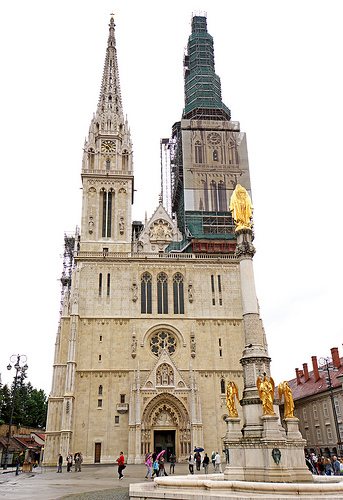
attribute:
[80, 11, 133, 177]
spire — pointy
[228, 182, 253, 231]
statue — golden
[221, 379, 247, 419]
statue — gold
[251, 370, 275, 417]
statue — gold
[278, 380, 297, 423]
statue — gold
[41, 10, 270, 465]
building — large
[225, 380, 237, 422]
angel statue — golden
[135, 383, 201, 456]
door way — arched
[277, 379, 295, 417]
statue — golden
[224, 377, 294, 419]
statues — golden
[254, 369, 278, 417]
statue — golden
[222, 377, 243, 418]
statue — golden